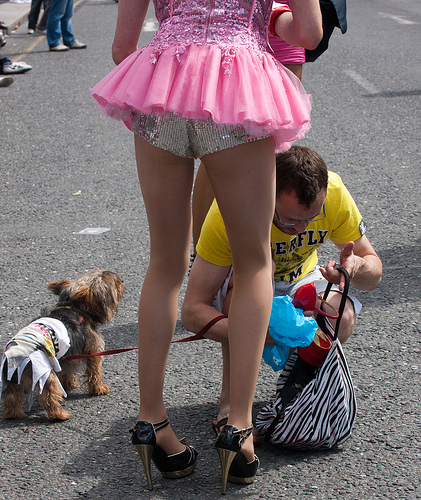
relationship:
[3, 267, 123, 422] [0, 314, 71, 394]
dog wearing shirt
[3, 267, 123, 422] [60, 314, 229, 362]
dog on leash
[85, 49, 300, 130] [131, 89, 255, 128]
tut with sequins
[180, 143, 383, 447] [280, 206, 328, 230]
man wearing glasses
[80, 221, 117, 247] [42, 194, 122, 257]
trash laying on asphalt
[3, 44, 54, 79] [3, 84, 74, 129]
lines painted on asphalt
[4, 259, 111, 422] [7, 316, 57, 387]
dog wearing white outfit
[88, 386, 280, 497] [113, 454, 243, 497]
two black high heeled shoes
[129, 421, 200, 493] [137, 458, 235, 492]
shoes with gold spiky heels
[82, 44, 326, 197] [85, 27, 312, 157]
short pink tulle tut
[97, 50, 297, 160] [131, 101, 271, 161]
silver sequined panties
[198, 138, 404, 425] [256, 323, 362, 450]
man crouched looking through zebra print bag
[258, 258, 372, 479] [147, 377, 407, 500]
zebra print bag on street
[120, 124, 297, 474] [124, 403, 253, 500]
two womens legs in black high heels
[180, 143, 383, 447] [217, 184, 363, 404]
man wearing glasses looking down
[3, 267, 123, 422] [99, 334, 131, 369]
dog on red leash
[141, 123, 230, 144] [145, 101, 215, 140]
shiny silver panties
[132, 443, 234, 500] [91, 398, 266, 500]
gold high heeled shoes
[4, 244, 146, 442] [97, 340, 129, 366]
little dog on a leash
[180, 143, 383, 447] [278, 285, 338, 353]
man holding a red shoe